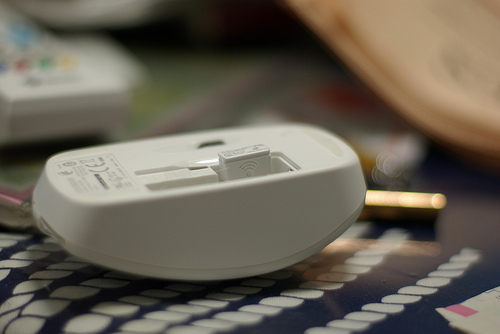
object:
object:
[355, 189, 449, 224]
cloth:
[0, 214, 500, 334]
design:
[165, 226, 412, 334]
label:
[51, 152, 136, 199]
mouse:
[27, 121, 372, 289]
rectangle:
[440, 302, 483, 318]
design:
[300, 246, 480, 334]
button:
[55, 52, 80, 71]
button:
[35, 53, 56, 70]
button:
[12, 55, 32, 72]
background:
[0, 0, 499, 133]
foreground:
[0, 151, 500, 334]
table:
[0, 0, 500, 334]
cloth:
[278, 0, 500, 181]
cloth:
[125, 39, 270, 129]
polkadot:
[256, 294, 308, 309]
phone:
[0, 0, 147, 147]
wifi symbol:
[217, 143, 273, 182]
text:
[52, 152, 138, 200]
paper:
[431, 282, 500, 334]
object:
[0, 186, 36, 214]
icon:
[15, 70, 85, 88]